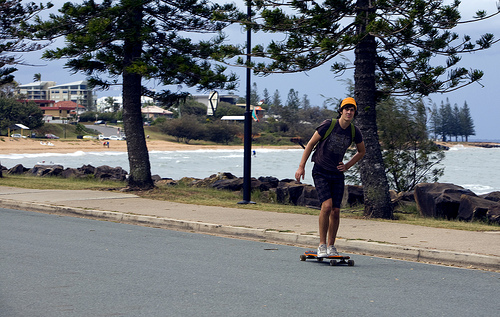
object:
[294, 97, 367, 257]
man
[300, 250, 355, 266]
skateboard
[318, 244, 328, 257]
shoes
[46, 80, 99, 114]
building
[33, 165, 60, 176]
rocks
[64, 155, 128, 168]
water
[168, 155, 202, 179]
background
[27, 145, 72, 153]
beach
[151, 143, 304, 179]
ocean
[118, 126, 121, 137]
person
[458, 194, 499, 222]
rock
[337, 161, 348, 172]
hand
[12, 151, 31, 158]
wave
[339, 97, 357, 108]
cap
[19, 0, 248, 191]
tree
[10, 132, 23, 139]
car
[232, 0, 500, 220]
tree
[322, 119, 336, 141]
strap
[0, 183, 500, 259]
sidewalk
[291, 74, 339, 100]
sky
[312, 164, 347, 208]
shorts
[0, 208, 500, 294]
road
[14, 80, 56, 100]
houses